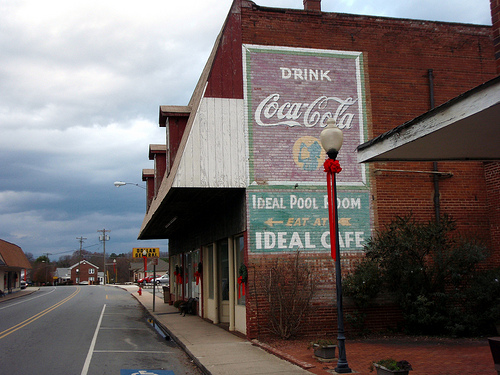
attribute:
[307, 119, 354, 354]
light — Short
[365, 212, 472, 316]
tree bush — dark green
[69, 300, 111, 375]
line — White 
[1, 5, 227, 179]
clouds — White 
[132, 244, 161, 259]
sign — Yellow , Black 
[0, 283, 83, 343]
lines — White 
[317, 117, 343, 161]
lamp cover — Clear 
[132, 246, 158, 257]
sign — black, yellow, "Dollar General"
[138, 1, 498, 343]
building — Tall 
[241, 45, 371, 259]
advertisement — Painted 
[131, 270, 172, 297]
vehicles — parked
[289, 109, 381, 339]
light — street light, long, black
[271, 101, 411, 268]
bow — Red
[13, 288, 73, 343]
line — Yellow 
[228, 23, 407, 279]
building — Tall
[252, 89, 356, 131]
coca-cola — White 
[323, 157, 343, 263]
pole — Black 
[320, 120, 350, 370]
light — Old fashioned 